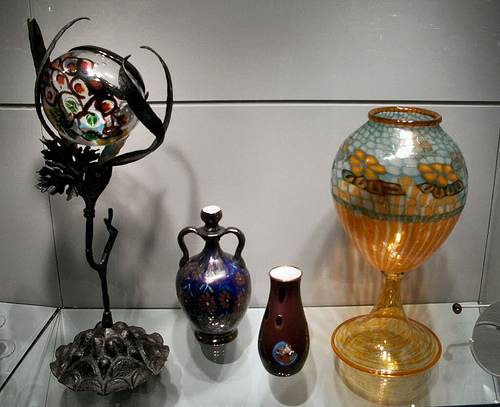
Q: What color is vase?
A: Brown.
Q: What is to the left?
A: Art in metal and glass.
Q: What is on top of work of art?
A: Glass globe.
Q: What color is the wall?
A: Grey.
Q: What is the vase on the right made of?
A: Glass.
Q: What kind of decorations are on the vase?
A: Flowers.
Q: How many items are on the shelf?
A: 4.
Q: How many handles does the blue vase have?
A: 2.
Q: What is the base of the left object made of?
A: Metal.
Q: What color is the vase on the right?
A: Orange.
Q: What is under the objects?
A: A shadow.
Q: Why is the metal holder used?
A: For decoration.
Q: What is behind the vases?
A: A white wall.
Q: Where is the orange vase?
A: On the far right.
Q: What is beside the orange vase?
A: Small brown vase.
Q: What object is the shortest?
A: Small brown vase.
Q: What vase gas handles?
A: The blue vase.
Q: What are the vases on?
A: A white table.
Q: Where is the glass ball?
A: On a metal stand.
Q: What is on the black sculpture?
A: A glass ball.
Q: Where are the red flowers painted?
A: Blue vase.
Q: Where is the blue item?
A: Second from left.